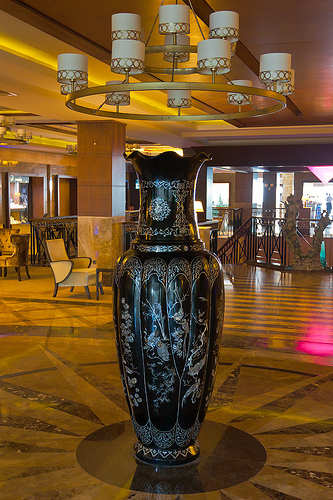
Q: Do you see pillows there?
A: No, there are no pillows.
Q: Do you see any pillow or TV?
A: No, there are no pillows or televisions.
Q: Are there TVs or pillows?
A: No, there are no pillows or tvs.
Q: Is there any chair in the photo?
A: Yes, there is a chair.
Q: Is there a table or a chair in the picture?
A: Yes, there is a chair.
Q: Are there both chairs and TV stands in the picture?
A: No, there is a chair but no TV stands.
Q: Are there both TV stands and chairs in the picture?
A: No, there is a chair but no TV stands.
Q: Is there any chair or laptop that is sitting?
A: Yes, the chair is sitting.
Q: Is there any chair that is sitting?
A: Yes, there is a chair that is sitting.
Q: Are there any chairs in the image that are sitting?
A: Yes, there is a chair that is sitting.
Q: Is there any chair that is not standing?
A: Yes, there is a chair that is sitting.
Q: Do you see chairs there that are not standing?
A: Yes, there is a chair that is sitting .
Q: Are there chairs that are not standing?
A: Yes, there is a chair that is sitting.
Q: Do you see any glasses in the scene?
A: No, there are no glasses.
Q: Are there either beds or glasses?
A: No, there are no glasses or beds.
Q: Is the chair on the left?
A: Yes, the chair is on the left of the image.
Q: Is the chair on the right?
A: No, the chair is on the left of the image.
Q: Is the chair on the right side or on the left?
A: The chair is on the left of the image.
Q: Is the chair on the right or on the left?
A: The chair is on the left of the image.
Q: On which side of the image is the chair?
A: The chair is on the left of the image.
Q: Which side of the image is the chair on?
A: The chair is on the left of the image.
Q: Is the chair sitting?
A: Yes, the chair is sitting.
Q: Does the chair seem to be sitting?
A: Yes, the chair is sitting.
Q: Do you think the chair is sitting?
A: Yes, the chair is sitting.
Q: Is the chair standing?
A: No, the chair is sitting.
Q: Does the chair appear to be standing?
A: No, the chair is sitting.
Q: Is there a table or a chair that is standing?
A: No, there is a chair but it is sitting.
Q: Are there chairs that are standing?
A: No, there is a chair but it is sitting.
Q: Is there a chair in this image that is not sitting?
A: No, there is a chair but it is sitting.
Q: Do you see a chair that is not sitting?
A: No, there is a chair but it is sitting.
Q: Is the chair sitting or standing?
A: The chair is sitting.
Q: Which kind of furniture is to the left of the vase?
A: The piece of furniture is a chair.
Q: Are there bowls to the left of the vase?
A: No, there is a chair to the left of the vase.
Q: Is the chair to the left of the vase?
A: Yes, the chair is to the left of the vase.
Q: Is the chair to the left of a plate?
A: No, the chair is to the left of the vase.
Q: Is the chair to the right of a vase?
A: No, the chair is to the left of a vase.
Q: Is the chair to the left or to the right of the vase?
A: The chair is to the left of the vase.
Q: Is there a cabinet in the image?
A: No, there are no cabinets.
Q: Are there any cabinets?
A: No, there are no cabinets.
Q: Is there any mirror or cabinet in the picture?
A: No, there are no cabinets or mirrors.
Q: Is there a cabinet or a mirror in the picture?
A: No, there are no cabinets or mirrors.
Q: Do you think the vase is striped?
A: Yes, the vase is striped.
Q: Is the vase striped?
A: Yes, the vase is striped.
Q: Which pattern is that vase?
A: The vase is striped.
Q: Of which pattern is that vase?
A: The vase is striped.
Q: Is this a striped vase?
A: Yes, this is a striped vase.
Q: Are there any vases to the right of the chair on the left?
A: Yes, there is a vase to the right of the chair.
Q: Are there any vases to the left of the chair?
A: No, the vase is to the right of the chair.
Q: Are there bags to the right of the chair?
A: No, there is a vase to the right of the chair.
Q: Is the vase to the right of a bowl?
A: No, the vase is to the right of the chair.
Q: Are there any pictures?
A: No, there are no pictures.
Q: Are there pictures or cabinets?
A: No, there are no pictures or cabinets.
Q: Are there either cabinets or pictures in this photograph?
A: No, there are no pictures or cabinets.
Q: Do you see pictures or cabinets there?
A: No, there are no pictures or cabinets.